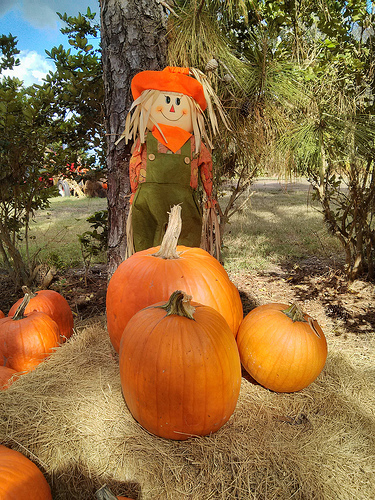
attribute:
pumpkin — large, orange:
[106, 205, 243, 357]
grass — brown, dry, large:
[1, 324, 374, 498]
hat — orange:
[130, 67, 213, 110]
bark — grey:
[97, 0, 195, 276]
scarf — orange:
[150, 125, 194, 153]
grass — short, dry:
[6, 184, 362, 266]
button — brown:
[185, 156, 193, 168]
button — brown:
[147, 153, 155, 159]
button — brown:
[141, 169, 147, 178]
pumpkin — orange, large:
[120, 293, 241, 439]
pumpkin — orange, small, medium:
[238, 305, 329, 395]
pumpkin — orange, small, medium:
[0, 296, 61, 372]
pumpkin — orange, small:
[0, 442, 55, 499]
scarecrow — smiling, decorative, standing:
[125, 66, 219, 249]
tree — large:
[95, 1, 177, 279]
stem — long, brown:
[156, 204, 183, 260]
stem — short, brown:
[158, 293, 199, 321]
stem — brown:
[17, 294, 29, 320]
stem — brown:
[285, 302, 306, 322]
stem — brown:
[24, 285, 35, 297]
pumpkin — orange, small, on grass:
[12, 290, 75, 344]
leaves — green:
[333, 178, 341, 186]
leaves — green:
[87, 8, 98, 20]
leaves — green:
[54, 11, 70, 21]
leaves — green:
[44, 48, 53, 55]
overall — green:
[130, 128, 206, 248]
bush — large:
[0, 32, 77, 290]